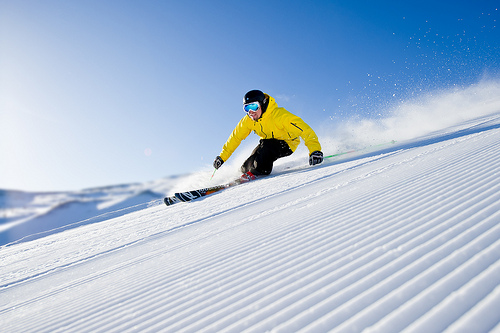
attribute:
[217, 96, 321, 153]
jacket — yellow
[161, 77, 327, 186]
guy — skiing down hill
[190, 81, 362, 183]
jacket — yellow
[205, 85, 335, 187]
man — skiing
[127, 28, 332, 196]
man — skiing